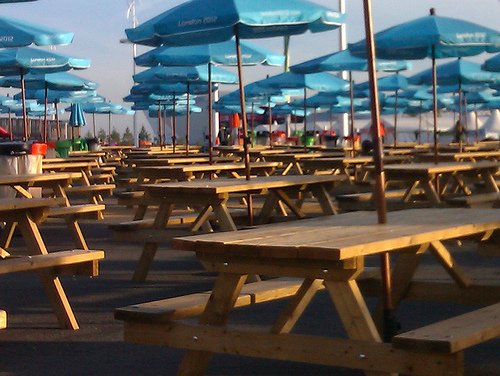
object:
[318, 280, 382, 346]
wood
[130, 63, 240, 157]
umbrella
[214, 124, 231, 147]
people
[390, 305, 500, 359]
benches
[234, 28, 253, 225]
pole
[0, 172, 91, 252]
table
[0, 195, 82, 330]
table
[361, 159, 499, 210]
table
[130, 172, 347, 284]
table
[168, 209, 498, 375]
picnic table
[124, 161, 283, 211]
table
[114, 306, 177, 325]
edge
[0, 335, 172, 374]
shade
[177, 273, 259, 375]
wood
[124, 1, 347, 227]
umbrella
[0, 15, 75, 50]
umbrella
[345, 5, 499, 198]
umbrella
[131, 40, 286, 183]
umbrella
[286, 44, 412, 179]
umbrella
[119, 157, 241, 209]
table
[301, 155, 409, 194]
table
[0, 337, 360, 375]
shade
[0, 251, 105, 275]
edge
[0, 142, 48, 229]
trash can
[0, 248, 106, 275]
picnic benches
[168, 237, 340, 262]
edge